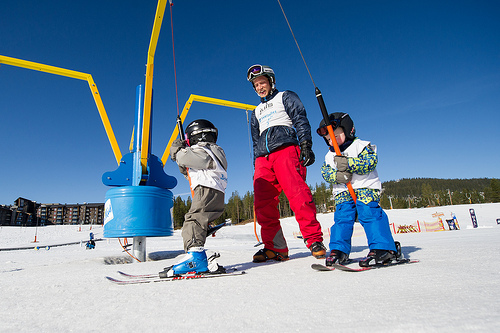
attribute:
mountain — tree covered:
[384, 169, 497, 199]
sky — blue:
[2, 0, 497, 179]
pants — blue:
[319, 187, 394, 264]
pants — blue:
[317, 200, 425, 268]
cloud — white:
[378, 95, 455, 119]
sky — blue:
[0, 0, 499, 205]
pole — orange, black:
[272, 2, 357, 207]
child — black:
[307, 112, 401, 274]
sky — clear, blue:
[321, 29, 456, 117]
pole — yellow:
[140, 0, 170, 170]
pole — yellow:
[0, 54, 124, 166]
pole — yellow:
[161, 94, 257, 162]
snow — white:
[381, 285, 436, 301]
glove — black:
[295, 133, 320, 170]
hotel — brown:
[0, 195, 110, 228]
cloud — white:
[0, 134, 497, 202]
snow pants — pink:
[229, 144, 331, 264]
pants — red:
[249, 141, 330, 246]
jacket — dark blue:
[234, 91, 319, 151]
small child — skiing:
[312, 111, 398, 264]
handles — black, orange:
[169, 92, 358, 205]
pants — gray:
[176, 172, 221, 242]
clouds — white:
[403, 61, 487, 176]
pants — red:
[245, 133, 305, 237]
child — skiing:
[166, 119, 231, 275]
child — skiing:
[314, 112, 400, 266]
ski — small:
[115, 268, 166, 281]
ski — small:
[105, 266, 245, 289]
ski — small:
[311, 256, 359, 274]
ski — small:
[334, 259, 418, 275]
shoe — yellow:
[252, 245, 288, 263]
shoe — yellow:
[309, 240, 325, 257]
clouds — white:
[0, 165, 113, 205]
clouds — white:
[168, 185, 258, 205]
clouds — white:
[0, 144, 499, 207]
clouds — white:
[413, 108, 498, 148]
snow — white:
[2, 199, 498, 328]